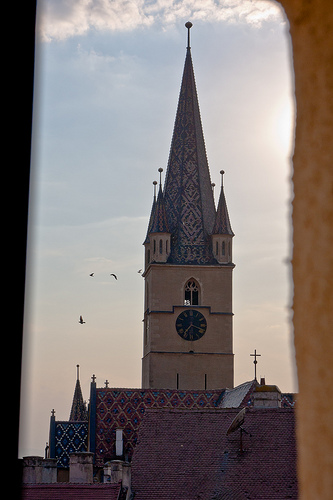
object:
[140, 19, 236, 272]
top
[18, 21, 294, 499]
building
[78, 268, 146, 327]
birds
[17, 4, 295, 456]
sky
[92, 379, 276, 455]
roof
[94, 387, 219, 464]
pattern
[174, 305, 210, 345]
clock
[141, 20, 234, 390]
tower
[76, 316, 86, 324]
bird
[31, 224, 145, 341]
air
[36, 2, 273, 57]
clouds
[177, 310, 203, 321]
gold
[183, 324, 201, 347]
hands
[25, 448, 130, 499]
chimneys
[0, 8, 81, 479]
left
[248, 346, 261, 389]
cross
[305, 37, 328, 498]
right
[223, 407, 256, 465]
satellite dish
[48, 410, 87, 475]
blue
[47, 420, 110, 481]
roof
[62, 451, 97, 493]
chimney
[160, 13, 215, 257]
steeple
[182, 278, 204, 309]
window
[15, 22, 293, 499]
church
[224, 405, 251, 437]
dish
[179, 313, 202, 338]
face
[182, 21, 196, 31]
ball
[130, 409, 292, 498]
roof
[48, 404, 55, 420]
cross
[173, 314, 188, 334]
numerals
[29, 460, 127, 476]
smokestacks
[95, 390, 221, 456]
mosaic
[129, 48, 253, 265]
spires